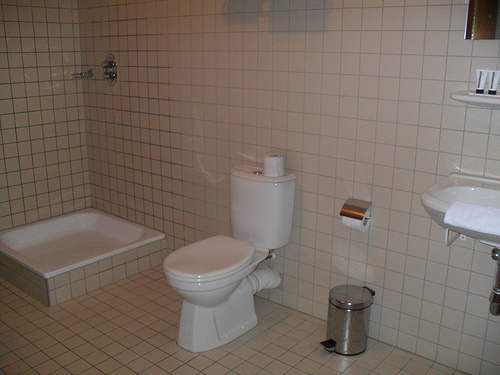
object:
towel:
[440, 202, 500, 236]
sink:
[418, 165, 500, 209]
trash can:
[318, 282, 375, 355]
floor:
[0, 265, 472, 374]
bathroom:
[0, 0, 498, 374]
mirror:
[460, 0, 499, 41]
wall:
[79, 0, 499, 374]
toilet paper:
[338, 213, 373, 235]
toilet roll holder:
[337, 198, 375, 223]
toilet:
[160, 165, 297, 354]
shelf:
[449, 88, 500, 114]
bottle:
[472, 66, 489, 94]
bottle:
[486, 67, 500, 98]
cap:
[474, 87, 485, 95]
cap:
[486, 88, 499, 98]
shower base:
[0, 206, 170, 304]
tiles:
[135, 310, 163, 327]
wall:
[0, 1, 90, 234]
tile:
[392, 146, 415, 172]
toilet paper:
[261, 155, 283, 179]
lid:
[160, 227, 258, 282]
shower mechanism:
[97, 51, 126, 89]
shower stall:
[0, 1, 174, 310]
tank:
[229, 164, 294, 251]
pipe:
[246, 266, 289, 297]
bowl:
[162, 268, 259, 313]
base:
[172, 266, 278, 354]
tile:
[134, 325, 163, 342]